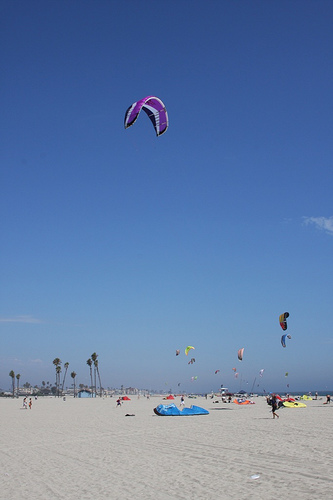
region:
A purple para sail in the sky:
[115, 92, 176, 134]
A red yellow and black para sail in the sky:
[278, 309, 290, 330]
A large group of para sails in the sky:
[168, 333, 293, 389]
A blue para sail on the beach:
[151, 401, 208, 415]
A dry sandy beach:
[0, 393, 332, 499]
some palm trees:
[8, 352, 101, 395]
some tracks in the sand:
[0, 420, 215, 456]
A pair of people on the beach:
[21, 397, 32, 409]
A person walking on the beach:
[177, 394, 186, 406]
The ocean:
[249, 389, 332, 394]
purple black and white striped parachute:
[119, 88, 175, 148]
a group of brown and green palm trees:
[4, 351, 110, 403]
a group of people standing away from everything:
[21, 395, 36, 409]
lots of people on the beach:
[101, 375, 332, 418]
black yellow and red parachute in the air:
[272, 301, 293, 334]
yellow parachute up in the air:
[183, 342, 196, 357]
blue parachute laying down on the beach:
[151, 401, 212, 420]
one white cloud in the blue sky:
[294, 201, 331, 241]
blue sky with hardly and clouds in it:
[3, 164, 295, 259]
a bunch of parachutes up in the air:
[167, 306, 313, 386]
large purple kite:
[123, 92, 171, 140]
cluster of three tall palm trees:
[86, 351, 104, 398]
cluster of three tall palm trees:
[50, 355, 69, 396]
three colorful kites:
[172, 344, 197, 366]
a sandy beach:
[0, 392, 331, 499]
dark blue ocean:
[190, 389, 332, 397]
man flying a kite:
[265, 392, 280, 421]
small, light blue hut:
[76, 388, 96, 399]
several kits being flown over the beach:
[165, 306, 300, 389]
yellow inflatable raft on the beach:
[281, 398, 309, 409]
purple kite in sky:
[122, 93, 184, 149]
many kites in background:
[169, 303, 301, 395]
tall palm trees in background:
[45, 351, 105, 386]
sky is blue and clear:
[71, 195, 194, 311]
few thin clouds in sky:
[7, 198, 326, 335]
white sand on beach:
[66, 422, 195, 497]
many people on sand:
[26, 376, 331, 447]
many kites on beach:
[126, 386, 321, 436]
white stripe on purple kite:
[117, 88, 175, 148]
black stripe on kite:
[122, 102, 169, 141]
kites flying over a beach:
[7, 75, 327, 454]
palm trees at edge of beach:
[1, 347, 109, 408]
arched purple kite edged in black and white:
[119, 89, 165, 135]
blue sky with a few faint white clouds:
[6, 2, 321, 379]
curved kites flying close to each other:
[164, 296, 299, 388]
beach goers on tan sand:
[14, 389, 326, 417]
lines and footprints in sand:
[10, 419, 313, 482]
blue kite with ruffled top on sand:
[151, 399, 207, 415]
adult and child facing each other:
[16, 387, 31, 406]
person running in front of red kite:
[113, 389, 130, 407]